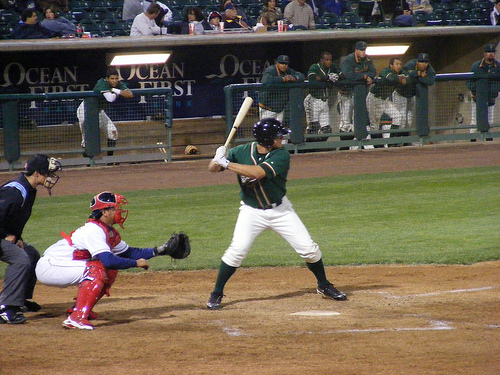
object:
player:
[259, 54, 306, 121]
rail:
[223, 72, 498, 154]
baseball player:
[75, 69, 133, 166]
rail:
[1, 88, 173, 171]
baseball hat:
[276, 55, 291, 63]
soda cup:
[276, 20, 288, 33]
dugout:
[2, 30, 496, 171]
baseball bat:
[212, 96, 254, 168]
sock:
[213, 260, 237, 295]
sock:
[307, 258, 333, 284]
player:
[208, 118, 347, 311]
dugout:
[0, 36, 499, 171]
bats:
[156, 143, 168, 164]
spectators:
[0, 0, 500, 38]